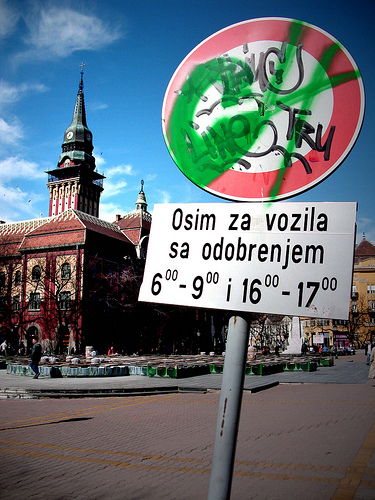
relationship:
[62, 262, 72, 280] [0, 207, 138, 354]
small window on building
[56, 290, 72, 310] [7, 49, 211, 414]
window on building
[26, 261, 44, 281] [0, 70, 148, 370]
window on building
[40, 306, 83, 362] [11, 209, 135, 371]
window on building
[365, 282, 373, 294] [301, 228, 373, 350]
window on building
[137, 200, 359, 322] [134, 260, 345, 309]
sign on times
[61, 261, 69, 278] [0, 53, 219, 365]
window on building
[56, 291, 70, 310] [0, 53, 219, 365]
window on building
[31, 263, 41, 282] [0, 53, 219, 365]
window on building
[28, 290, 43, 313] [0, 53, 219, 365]
window on building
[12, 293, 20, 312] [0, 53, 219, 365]
window on building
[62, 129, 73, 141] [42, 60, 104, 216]
clock on tower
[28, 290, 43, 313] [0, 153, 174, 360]
window on building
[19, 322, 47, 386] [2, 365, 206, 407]
people on side walk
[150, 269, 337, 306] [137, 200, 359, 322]
numbers on bottom of sign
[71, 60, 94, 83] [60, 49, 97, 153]
cross on dome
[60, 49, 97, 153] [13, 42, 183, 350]
dome on church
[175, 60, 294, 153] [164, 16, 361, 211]
graffiti over graffiti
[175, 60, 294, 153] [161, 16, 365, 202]
graffiti on sign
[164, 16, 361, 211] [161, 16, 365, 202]
graffiti on sign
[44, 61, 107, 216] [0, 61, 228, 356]
steeple on church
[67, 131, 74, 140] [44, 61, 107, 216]
clock on steeple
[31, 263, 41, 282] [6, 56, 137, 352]
window on church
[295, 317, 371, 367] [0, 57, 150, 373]
storefronts in building